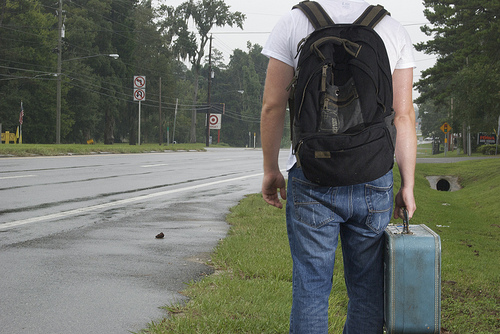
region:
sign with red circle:
[127, 71, 156, 95]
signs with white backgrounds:
[129, 73, 153, 113]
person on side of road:
[167, 16, 465, 330]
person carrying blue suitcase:
[244, 0, 478, 332]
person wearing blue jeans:
[258, 7, 423, 331]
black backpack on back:
[247, 5, 416, 205]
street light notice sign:
[424, 116, 469, 161]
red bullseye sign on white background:
[199, 104, 231, 143]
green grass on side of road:
[130, 188, 275, 331]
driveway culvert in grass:
[424, 142, 483, 232]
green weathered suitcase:
[378, 192, 455, 332]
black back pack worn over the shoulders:
[285, 1, 402, 193]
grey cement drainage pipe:
[424, 170, 468, 197]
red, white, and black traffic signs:
[126, 70, 157, 152]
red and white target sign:
[203, 108, 225, 145]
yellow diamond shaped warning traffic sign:
[436, 120, 456, 153]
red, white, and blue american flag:
[14, 96, 29, 146]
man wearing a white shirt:
[246, 0, 456, 332]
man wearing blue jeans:
[248, 0, 448, 331]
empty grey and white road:
[1, 147, 290, 332]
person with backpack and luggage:
[217, 16, 467, 321]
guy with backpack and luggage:
[217, 8, 461, 309]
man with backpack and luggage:
[239, 8, 456, 315]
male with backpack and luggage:
[233, 8, 465, 313]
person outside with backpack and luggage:
[237, 3, 449, 296]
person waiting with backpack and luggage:
[256, 13, 461, 313]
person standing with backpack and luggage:
[251, 11, 458, 315]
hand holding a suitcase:
[372, 184, 454, 329]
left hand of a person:
[258, 166, 293, 218]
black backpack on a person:
[287, 2, 397, 187]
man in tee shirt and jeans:
[226, 4, 431, 326]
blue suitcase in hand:
[376, 197, 447, 332]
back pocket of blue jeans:
[349, 177, 399, 242]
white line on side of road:
[85, 168, 225, 218]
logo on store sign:
[198, 104, 233, 136]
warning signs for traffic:
[126, 67, 158, 107]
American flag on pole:
[10, 94, 32, 145]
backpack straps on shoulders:
[290, 1, 395, 34]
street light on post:
[75, 40, 137, 67]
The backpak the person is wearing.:
[275, 15, 407, 182]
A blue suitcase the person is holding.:
[377, 211, 447, 332]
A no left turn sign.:
[133, 69, 146, 89]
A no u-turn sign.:
[131, 88, 146, 102]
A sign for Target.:
[204, 107, 222, 132]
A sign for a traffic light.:
[440, 120, 456, 141]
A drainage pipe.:
[429, 167, 462, 202]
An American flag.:
[17, 101, 27, 151]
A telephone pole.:
[198, 31, 214, 154]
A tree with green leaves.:
[411, 4, 498, 150]